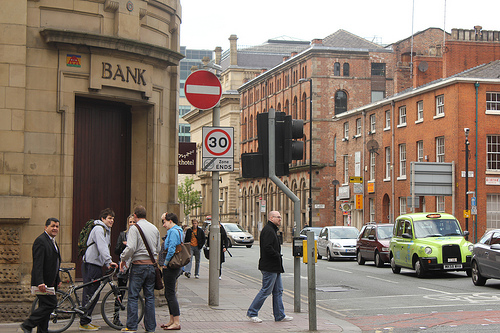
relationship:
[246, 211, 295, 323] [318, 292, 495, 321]
man waiting to cross street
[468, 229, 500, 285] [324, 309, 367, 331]
cars parked along curb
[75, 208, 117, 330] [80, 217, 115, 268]
man in hoodie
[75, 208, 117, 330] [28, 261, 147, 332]
man holding bicycle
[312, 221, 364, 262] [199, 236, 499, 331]
silver sedan on road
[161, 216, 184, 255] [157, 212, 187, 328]
blue jacket worn by lady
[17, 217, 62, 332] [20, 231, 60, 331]
man in suit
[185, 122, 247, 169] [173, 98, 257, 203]
writing on sign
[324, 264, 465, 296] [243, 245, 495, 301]
lines on road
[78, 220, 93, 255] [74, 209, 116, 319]
backpack on man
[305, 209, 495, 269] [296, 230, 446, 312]
cars in street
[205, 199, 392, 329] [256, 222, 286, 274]
man in jacket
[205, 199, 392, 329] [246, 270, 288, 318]
man in pants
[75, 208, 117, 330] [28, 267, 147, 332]
man with bicycle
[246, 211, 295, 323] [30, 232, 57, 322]
man with suit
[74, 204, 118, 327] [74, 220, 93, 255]
man with backpack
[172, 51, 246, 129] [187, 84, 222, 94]
sign with bar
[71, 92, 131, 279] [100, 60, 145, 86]
door under bank sign